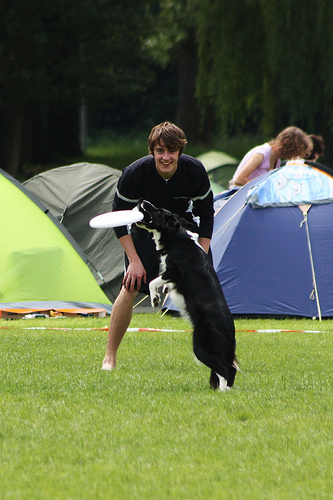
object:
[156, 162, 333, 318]
tent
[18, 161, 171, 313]
tent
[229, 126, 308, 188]
woman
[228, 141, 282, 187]
shirt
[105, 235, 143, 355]
leg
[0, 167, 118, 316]
tent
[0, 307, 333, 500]
ground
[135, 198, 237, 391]
dog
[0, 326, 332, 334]
rope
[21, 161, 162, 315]
gray tent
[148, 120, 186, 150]
hair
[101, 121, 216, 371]
guy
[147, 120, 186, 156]
hair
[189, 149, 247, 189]
tent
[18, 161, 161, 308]
tent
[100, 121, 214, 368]
boy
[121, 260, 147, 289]
hand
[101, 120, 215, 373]
man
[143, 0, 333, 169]
tree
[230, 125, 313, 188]
woman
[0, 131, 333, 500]
grass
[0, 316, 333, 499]
ground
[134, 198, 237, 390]
black dog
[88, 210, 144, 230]
frisbee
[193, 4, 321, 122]
leaves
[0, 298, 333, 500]
ground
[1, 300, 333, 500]
field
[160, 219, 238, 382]
hair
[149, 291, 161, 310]
paw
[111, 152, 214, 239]
shirt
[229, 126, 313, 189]
boy